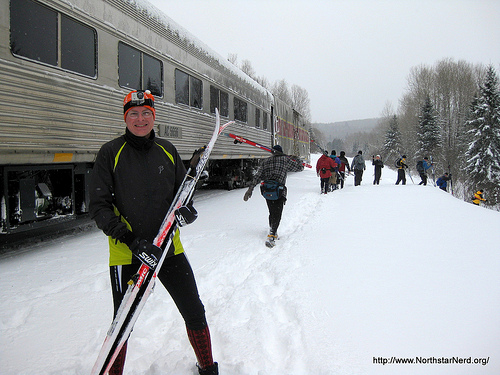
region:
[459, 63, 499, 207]
A snow covered evergreen tree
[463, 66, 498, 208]
A snow covered pine tree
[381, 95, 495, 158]
Grouping of snow covered trees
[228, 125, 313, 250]
A person wearing a black and white plaid shirt carrying their red skiis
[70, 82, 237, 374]
A person dressed in skiing attire holding a pair of skiis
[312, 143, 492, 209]
A group of people walking in a line in the snow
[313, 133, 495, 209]
A group of people walking down a snow covered hill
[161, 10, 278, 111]
Snow and ice on top of a stainless steel passenger train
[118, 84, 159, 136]
A person wearing a go-pro camera on their head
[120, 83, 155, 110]
Orange winter hat with a Go-Pro camera strapped to it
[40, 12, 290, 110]
train cars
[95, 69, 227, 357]
man holding skis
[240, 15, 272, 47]
white clouds in blue sky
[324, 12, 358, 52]
white clouds in blue sky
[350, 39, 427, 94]
white clouds in blue sky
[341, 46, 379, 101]
white clouds in blue sky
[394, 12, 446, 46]
white clouds in blue sky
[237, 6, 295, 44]
white clouds in blue sky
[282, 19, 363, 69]
white clouds in blue sky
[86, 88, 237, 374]
A man holding skis.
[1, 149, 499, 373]
A large area of snow.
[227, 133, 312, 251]
A man carrying skis.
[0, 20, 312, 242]
A silver train in the snow.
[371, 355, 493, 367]
A black website address.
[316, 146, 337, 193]
A person wearing red.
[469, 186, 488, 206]
A person wearing yellow.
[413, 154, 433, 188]
A person wearing blue.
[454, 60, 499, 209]
A pine tree with snow on it.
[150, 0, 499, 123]
A gray overcast sky.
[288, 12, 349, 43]
white clouds in blue sky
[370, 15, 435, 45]
white clouds in blue sky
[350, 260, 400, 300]
white snow on the ground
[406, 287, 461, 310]
white snow on the ground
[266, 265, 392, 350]
white snow on the ground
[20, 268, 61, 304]
white snow on the ground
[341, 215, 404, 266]
white snow on the ground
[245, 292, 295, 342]
white snow on the ground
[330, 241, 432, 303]
white snow on the ground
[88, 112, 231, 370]
a long pair of white skis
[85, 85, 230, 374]
a woman with her skis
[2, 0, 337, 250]
a long silver train in the snow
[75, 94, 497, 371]
a group of skiiers on a trail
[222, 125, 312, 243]
a man carrying his red skis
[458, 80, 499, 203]
a tall snow covered tree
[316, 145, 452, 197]
a crowd of people heading down a hill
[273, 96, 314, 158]
a snow covered train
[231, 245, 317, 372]
a path in the snow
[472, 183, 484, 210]
a man in a yellow jacket